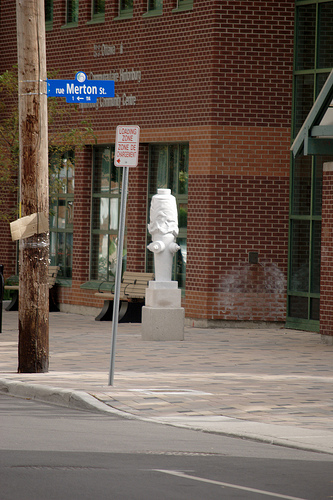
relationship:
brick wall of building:
[0, 1, 288, 324] [0, 0, 329, 341]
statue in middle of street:
[138, 185, 186, 345] [1, 393, 43, 432]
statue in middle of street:
[138, 185, 186, 345] [49, 404, 127, 441]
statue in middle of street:
[138, 185, 186, 345] [123, 435, 245, 498]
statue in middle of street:
[138, 185, 186, 345] [2, 440, 75, 496]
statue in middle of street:
[138, 185, 186, 345] [264, 461, 332, 499]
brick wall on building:
[0, 1, 288, 324] [0, 0, 329, 341]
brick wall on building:
[206, 60, 280, 221] [0, 0, 329, 341]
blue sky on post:
[48, 70, 120, 109] [106, 164, 127, 380]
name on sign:
[54, 82, 106, 95] [44, 70, 115, 104]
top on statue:
[153, 185, 175, 195] [138, 185, 186, 345]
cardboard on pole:
[8, 209, 48, 243] [9, 1, 55, 373]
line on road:
[148, 458, 308, 500] [3, 400, 331, 497]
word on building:
[119, 89, 140, 108] [1, 1, 290, 321]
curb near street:
[4, 387, 109, 415] [5, 344, 318, 490]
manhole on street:
[140, 448, 225, 457] [0, 392, 331, 498]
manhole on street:
[8, 461, 110, 471] [0, 392, 331, 498]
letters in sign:
[66, 83, 99, 96] [48, 72, 117, 97]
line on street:
[148, 458, 308, 500] [2, 384, 321, 500]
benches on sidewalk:
[9, 226, 163, 346] [5, 299, 332, 470]